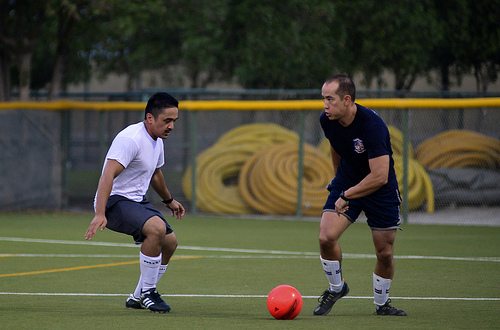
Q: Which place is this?
A: It is a field.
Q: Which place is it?
A: It is a field.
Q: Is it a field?
A: Yes, it is a field.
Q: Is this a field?
A: Yes, it is a field.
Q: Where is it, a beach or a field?
A: It is a field.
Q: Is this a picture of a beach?
A: No, the picture is showing a field.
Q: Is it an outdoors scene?
A: Yes, it is outdoors.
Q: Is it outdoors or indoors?
A: It is outdoors.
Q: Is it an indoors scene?
A: No, it is outdoors.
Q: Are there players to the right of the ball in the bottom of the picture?
A: Yes, there is a player to the right of the ball.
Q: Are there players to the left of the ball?
A: No, the player is to the right of the ball.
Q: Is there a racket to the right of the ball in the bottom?
A: No, there is a player to the right of the ball.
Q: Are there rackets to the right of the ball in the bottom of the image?
A: No, there is a player to the right of the ball.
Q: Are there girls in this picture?
A: No, there are no girls.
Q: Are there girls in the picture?
A: No, there are no girls.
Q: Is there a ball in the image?
A: Yes, there is a ball.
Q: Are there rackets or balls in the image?
A: Yes, there is a ball.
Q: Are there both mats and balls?
A: No, there is a ball but no mats.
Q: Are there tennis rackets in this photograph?
A: No, there are no tennis rackets.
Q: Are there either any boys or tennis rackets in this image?
A: No, there are no tennis rackets or boys.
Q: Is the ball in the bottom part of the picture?
A: Yes, the ball is in the bottom of the image.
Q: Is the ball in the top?
A: No, the ball is in the bottom of the image.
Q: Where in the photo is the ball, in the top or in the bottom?
A: The ball is in the bottom of the image.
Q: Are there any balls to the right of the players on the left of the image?
A: Yes, there is a ball to the right of the players.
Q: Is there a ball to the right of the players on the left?
A: Yes, there is a ball to the right of the players.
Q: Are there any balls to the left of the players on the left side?
A: No, the ball is to the right of the players.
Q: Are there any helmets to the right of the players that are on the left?
A: No, there is a ball to the right of the players.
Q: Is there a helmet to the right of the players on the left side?
A: No, there is a ball to the right of the players.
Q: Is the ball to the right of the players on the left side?
A: Yes, the ball is to the right of the players.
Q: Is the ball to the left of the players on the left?
A: No, the ball is to the right of the players.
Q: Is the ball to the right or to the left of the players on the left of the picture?
A: The ball is to the right of the players.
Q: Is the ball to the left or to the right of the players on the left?
A: The ball is to the right of the players.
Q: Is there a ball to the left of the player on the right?
A: Yes, there is a ball to the left of the player.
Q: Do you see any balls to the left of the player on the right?
A: Yes, there is a ball to the left of the player.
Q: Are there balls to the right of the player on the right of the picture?
A: No, the ball is to the left of the player.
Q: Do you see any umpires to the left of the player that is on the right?
A: No, there is a ball to the left of the player.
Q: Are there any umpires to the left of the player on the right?
A: No, there is a ball to the left of the player.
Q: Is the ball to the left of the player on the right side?
A: Yes, the ball is to the left of the player.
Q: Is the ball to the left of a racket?
A: No, the ball is to the left of the player.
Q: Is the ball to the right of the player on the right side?
A: No, the ball is to the left of the player.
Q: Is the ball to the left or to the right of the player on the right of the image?
A: The ball is to the left of the player.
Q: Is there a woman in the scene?
A: No, there are no women.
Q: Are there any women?
A: No, there are no women.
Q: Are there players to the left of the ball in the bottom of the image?
A: Yes, there are players to the left of the ball.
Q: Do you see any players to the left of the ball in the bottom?
A: Yes, there are players to the left of the ball.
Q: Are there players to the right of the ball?
A: No, the players are to the left of the ball.